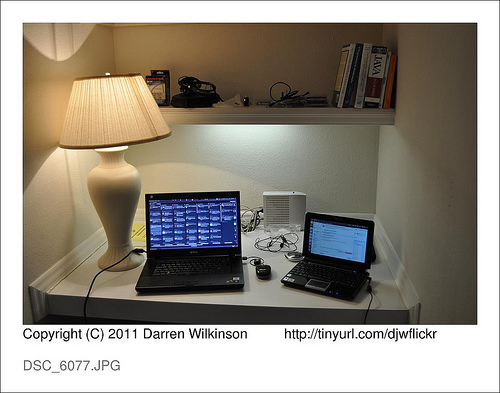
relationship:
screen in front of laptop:
[148, 197, 240, 249] [133, 191, 245, 292]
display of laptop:
[157, 203, 218, 242] [133, 191, 245, 292]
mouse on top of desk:
[257, 264, 272, 279] [45, 213, 413, 325]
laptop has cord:
[133, 191, 245, 292] [82, 247, 144, 326]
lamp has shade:
[62, 78, 174, 272] [31, 19, 132, 195]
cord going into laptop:
[82, 247, 144, 326] [133, 191, 245, 292]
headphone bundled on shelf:
[178, 76, 221, 97] [112, 25, 399, 127]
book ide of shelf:
[334, 42, 356, 111] [112, 25, 399, 127]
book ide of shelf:
[365, 44, 386, 106] [112, 25, 399, 127]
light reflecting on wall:
[186, 122, 300, 163] [22, 24, 477, 326]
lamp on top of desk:
[62, 78, 174, 272] [45, 213, 413, 325]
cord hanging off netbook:
[362, 274, 373, 325] [282, 212, 375, 303]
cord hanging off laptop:
[82, 247, 144, 326] [133, 191, 245, 292]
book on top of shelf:
[334, 42, 356, 111] [112, 25, 399, 127]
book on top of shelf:
[365, 44, 386, 106] [112, 25, 399, 127]